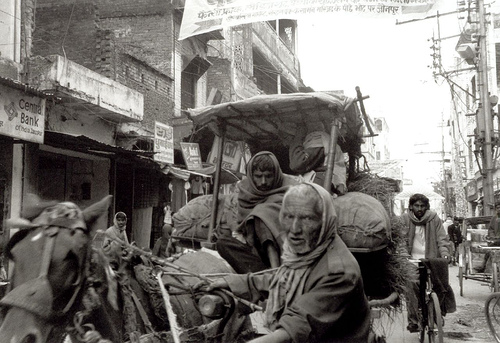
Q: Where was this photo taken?
A: A town street.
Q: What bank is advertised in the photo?
A: Central Bank.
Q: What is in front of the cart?
A: Horse.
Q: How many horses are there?
A: One.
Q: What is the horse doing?
A: Pulling the cart.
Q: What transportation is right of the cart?
A: Bicycle.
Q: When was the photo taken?
A: During the day.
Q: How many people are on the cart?
A: Two.